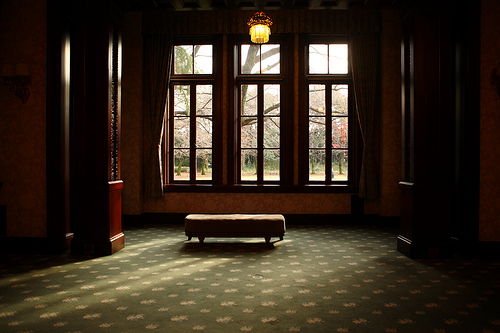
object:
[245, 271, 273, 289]
part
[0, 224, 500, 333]
floor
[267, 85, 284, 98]
part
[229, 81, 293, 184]
window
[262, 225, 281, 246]
part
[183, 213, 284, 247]
stand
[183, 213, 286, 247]
bench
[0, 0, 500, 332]
room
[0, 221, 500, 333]
carpet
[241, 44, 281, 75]
glass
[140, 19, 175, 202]
curtain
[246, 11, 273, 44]
light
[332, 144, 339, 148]
flower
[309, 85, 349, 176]
tree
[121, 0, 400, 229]
wall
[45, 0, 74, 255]
pole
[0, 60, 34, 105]
lamp